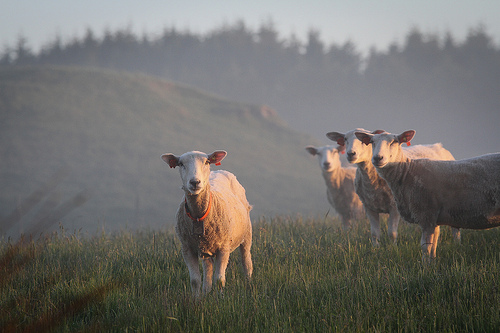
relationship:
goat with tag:
[160, 150, 254, 305] [213, 150, 224, 165]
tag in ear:
[213, 150, 224, 165] [202, 146, 227, 167]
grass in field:
[0, 64, 500, 330] [1, 16, 498, 330]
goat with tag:
[160, 150, 254, 305] [213, 152, 220, 166]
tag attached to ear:
[213, 152, 220, 166] [205, 151, 225, 162]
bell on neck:
[192, 211, 206, 223] [181, 182, 209, 217]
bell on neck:
[192, 211, 206, 223] [383, 154, 419, 191]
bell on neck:
[192, 211, 206, 223] [353, 160, 375, 181]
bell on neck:
[192, 211, 206, 223] [323, 166, 345, 189]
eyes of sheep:
[391, 137, 398, 146] [377, 129, 497, 249]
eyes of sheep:
[362, 137, 372, 144] [343, 135, 393, 240]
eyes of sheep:
[333, 145, 343, 156] [304, 145, 356, 224]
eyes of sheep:
[203, 155, 209, 165] [161, 148, 253, 295]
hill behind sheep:
[1, 62, 342, 240] [161, 148, 253, 295]